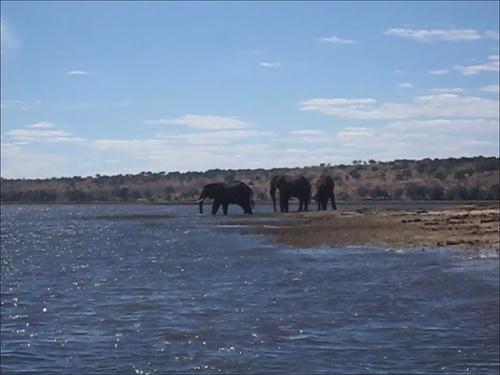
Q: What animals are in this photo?
A: Elephants.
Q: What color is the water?
A: Blue.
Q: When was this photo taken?
A: Daytime.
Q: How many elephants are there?
A: Three.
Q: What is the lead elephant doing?
A: Drinking water.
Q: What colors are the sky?
A: Blue, white.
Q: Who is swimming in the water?
A: No one.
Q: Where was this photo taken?
A: Wild park.